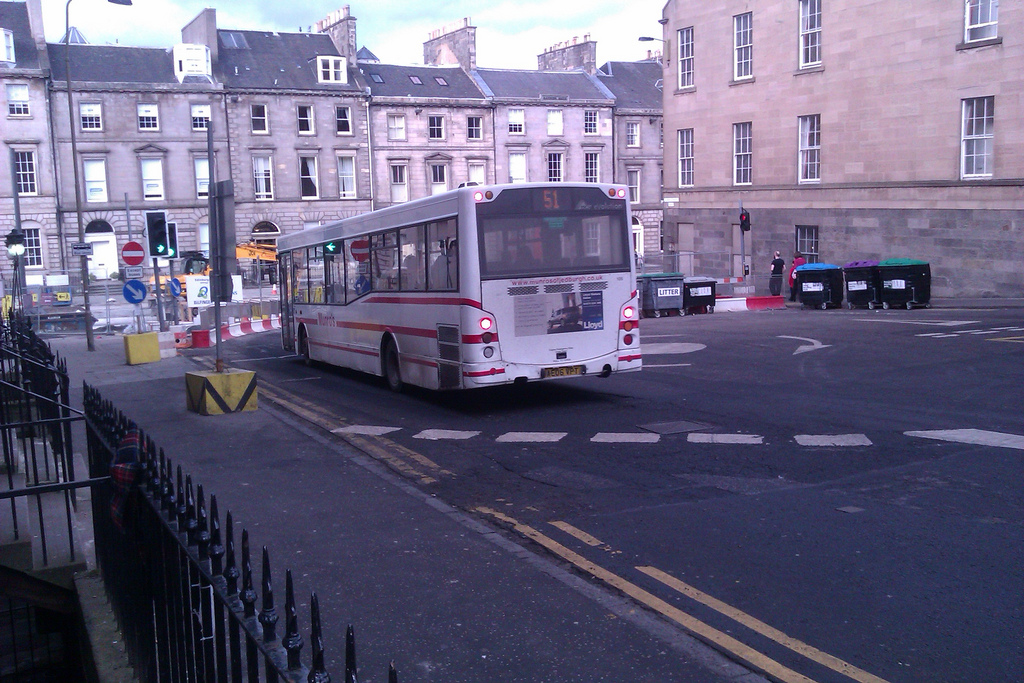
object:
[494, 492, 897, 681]
lines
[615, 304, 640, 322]
headlight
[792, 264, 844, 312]
trashcans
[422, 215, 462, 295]
window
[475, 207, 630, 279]
window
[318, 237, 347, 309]
window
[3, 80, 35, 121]
window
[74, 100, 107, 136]
window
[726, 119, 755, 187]
window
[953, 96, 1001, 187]
window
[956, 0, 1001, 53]
window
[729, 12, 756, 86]
window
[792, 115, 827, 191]
window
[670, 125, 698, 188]
window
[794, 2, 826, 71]
window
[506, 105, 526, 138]
window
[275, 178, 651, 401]
bus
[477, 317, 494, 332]
light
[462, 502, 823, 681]
lines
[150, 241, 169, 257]
light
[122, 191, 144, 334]
pole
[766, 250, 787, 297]
people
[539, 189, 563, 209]
number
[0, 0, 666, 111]
roof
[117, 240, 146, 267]
sign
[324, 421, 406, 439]
square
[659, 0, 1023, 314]
building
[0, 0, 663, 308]
building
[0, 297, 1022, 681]
street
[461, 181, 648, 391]
back